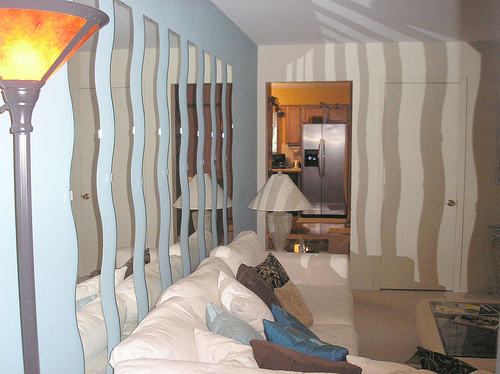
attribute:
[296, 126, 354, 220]
refrigerator — stainless, steel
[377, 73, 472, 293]
door — White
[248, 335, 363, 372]
pillow — brown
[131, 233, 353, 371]
sofa — white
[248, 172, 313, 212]
lampshade — Small, White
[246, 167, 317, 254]
lamp — white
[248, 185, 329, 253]
lamp — white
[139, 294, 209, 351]
couch — white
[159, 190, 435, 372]
couch — white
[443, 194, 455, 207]
door knob — small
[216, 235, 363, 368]
pillows — several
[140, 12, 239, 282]
mirrors — decorative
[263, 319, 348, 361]
pillow — dark, blue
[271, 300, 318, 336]
pillow — dark, blue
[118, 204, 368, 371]
sofa — white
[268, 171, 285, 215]
stripe — brown, white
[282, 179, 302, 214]
stripe — brown, white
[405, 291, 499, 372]
coffee table — cream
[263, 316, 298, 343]
pillow part — teal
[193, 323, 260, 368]
pillow — white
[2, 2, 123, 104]
lampshade — Large, orange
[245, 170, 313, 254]
lamp — Small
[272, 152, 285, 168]
coffee maker — black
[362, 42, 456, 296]
stripes — brown, white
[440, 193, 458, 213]
doorknob — small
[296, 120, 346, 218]
refrigerator — Grey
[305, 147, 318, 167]
ice maker — black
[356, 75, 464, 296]
door — white